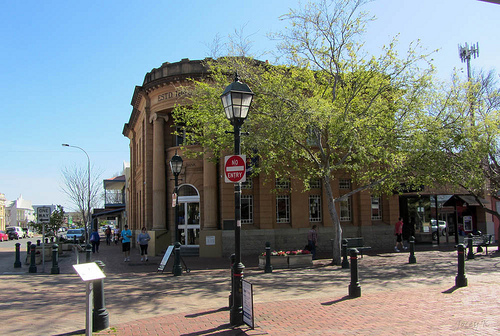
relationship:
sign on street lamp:
[221, 151, 249, 183] [215, 64, 249, 327]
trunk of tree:
[330, 211, 344, 265] [169, 0, 499, 265]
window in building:
[232, 192, 255, 225] [122, 56, 500, 263]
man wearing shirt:
[116, 221, 134, 263] [119, 229, 134, 245]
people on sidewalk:
[116, 222, 152, 262] [32, 238, 153, 270]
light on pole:
[169, 153, 184, 180] [171, 174, 182, 278]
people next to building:
[116, 222, 152, 262] [122, 56, 500, 263]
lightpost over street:
[56, 142, 93, 253] [0, 233, 51, 272]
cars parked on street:
[1, 223, 35, 243] [0, 233, 51, 272]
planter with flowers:
[257, 246, 315, 270] [261, 249, 311, 256]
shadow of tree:
[212, 266, 442, 289] [169, 0, 499, 265]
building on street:
[122, 56, 500, 263] [0, 233, 51, 272]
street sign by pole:
[159, 244, 190, 274] [171, 174, 182, 278]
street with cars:
[0, 233, 51, 272] [1, 223, 35, 243]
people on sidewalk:
[137, 225, 153, 263] [32, 238, 153, 270]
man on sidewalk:
[116, 221, 134, 263] [32, 238, 153, 270]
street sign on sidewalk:
[159, 244, 190, 274] [32, 238, 153, 270]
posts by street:
[12, 234, 66, 273] [0, 233, 51, 272]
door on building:
[175, 200, 202, 248] [122, 56, 500, 263]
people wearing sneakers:
[137, 225, 153, 263] [140, 258, 149, 263]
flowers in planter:
[261, 249, 311, 256] [257, 246, 315, 270]